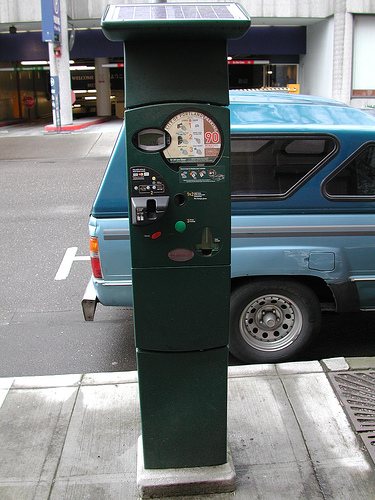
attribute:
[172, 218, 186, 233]
button — green, round, bright green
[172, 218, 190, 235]
button — green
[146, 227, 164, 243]
button — red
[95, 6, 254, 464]
meter — parking, large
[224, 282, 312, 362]
tire — back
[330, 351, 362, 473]
plate — metal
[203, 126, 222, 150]
number — 90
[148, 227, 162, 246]
button — small, red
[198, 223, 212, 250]
slot — coin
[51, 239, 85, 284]
line — white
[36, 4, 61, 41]
sign — blue, white stop, red 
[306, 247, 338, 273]
cover — gas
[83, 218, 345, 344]
truck — light blue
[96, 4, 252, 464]
post — green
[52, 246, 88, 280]
lines — white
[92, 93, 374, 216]
camper — dark blue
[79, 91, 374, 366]
truck — parked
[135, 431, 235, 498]
base — cement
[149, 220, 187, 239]
buttons — green and red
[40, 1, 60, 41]
sign — blue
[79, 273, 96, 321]
bumper — metal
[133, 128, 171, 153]
display — digital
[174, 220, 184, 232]
button — green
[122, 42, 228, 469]
post — green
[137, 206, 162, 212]
slot — credit card slot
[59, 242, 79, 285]
line painted —  white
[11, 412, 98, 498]
sidewalk — concrete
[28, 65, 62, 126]
window — one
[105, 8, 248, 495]
meter — green parking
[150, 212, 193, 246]
button — A green and red, parking 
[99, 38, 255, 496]
meter — parking 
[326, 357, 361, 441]
drain — metal 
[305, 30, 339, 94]
wall — brick 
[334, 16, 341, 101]
wall — brick 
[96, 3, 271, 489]
meter — tall green parking , tall, green, parking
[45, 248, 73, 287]
spot — white painted line indicating parking 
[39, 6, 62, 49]
sign — blue 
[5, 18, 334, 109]
garage — parking 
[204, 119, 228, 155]
number — 9 , 0, red 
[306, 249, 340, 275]
cover — blue gas door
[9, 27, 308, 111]
garage — parking , entrance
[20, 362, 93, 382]
curb —  painted bright red, rounded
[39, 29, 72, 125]
pole — white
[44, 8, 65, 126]
center — green 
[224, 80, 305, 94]
barrier — red, white, traffic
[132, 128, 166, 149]
display — digital